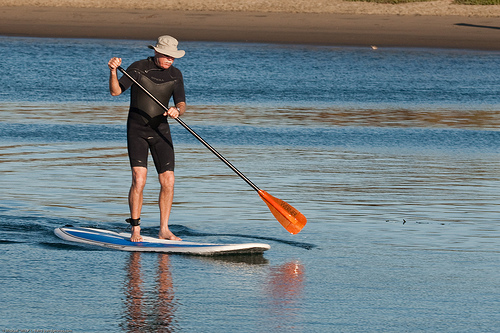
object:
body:
[106, 35, 189, 244]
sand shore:
[0, 0, 500, 52]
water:
[0, 49, 499, 333]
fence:
[349, 36, 393, 105]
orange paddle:
[111, 62, 307, 235]